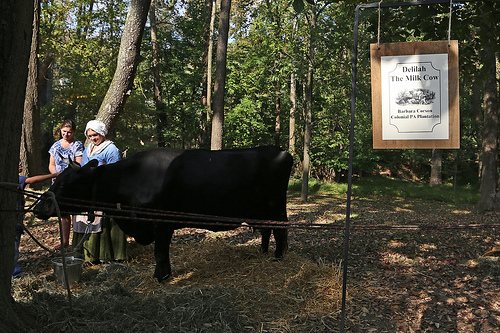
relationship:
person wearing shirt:
[81, 121, 120, 206] [81, 139, 121, 166]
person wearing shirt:
[48, 120, 82, 175] [46, 140, 80, 174]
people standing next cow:
[13, 119, 129, 269] [31, 144, 293, 281]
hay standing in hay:
[126, 240, 350, 325] [126, 240, 350, 325]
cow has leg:
[39, 140, 304, 275] [154, 230, 174, 280]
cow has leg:
[39, 140, 304, 275] [260, 225, 270, 250]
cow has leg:
[39, 140, 304, 275] [277, 219, 289, 258]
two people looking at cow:
[31, 115, 296, 287] [39, 140, 304, 275]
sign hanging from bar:
[370, 40, 460, 149] [338, 0, 432, 332]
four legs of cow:
[139, 221, 296, 274] [39, 140, 304, 275]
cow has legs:
[31, 144, 293, 281] [252, 212, 307, 270]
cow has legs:
[31, 144, 293, 281] [143, 229, 186, 294]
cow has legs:
[31, 144, 293, 281] [51, 215, 79, 257]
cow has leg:
[31, 144, 293, 281] [274, 224, 289, 259]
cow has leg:
[31, 144, 293, 281] [257, 226, 270, 253]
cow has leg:
[31, 144, 293, 281] [154, 223, 175, 284]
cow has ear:
[31, 144, 293, 281] [60, 153, 82, 170]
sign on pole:
[370, 40, 460, 149] [335, 33, 362, 332]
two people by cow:
[46, 115, 128, 264] [31, 144, 293, 281]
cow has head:
[31, 144, 293, 281] [31, 154, 103, 221]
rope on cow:
[16, 217, 96, 259] [31, 144, 293, 281]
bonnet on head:
[83, 118, 108, 138] [81, 114, 112, 152]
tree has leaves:
[269, 33, 286, 144] [227, 42, 276, 144]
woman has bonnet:
[73, 121, 127, 263] [84, 119, 109, 137]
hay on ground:
[183, 250, 345, 328] [18, 220, 498, 327]